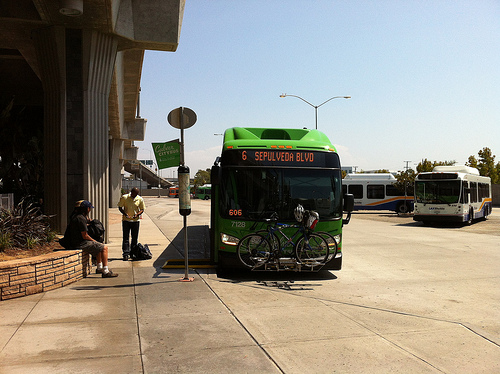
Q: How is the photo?
A: Clear.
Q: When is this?
A: Daytime.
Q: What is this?
A: Bus.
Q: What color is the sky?
A: Blue.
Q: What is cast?
A: Shadow.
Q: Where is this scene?
A: At a bus stop.